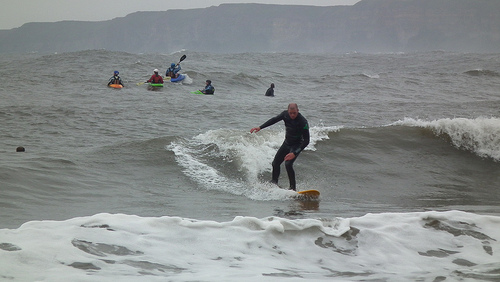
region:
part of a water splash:
[421, 115, 463, 148]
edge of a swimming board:
[297, 170, 319, 206]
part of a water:
[206, 196, 248, 238]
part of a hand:
[282, 145, 294, 162]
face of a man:
[278, 91, 300, 121]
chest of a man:
[285, 126, 301, 147]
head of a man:
[287, 99, 299, 114]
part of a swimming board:
[106, 82, 122, 92]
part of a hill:
[322, 14, 367, 49]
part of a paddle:
[174, 52, 189, 64]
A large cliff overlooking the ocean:
[14, 8, 491, 64]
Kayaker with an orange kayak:
[93, 62, 128, 94]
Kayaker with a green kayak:
[142, 62, 168, 97]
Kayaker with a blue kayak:
[161, 55, 203, 90]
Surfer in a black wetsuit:
[256, 97, 326, 222]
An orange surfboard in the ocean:
[279, 165, 341, 233]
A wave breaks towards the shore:
[107, 95, 492, 211]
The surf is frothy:
[25, 197, 465, 266]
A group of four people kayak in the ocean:
[76, 43, 223, 117]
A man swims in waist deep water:
[258, 77, 278, 99]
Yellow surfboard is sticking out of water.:
[288, 172, 330, 217]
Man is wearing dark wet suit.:
[257, 102, 337, 247]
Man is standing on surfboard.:
[264, 115, 355, 278]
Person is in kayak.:
[171, 52, 188, 96]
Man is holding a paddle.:
[172, 35, 199, 100]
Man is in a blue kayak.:
[164, 53, 202, 133]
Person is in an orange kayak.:
[104, 50, 144, 154]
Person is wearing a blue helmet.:
[106, 63, 149, 109]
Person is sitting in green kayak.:
[146, 50, 189, 130]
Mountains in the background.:
[66, 7, 389, 36]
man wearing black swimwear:
[254, 92, 332, 222]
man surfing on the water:
[256, 90, 342, 224]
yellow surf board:
[281, 186, 379, 221]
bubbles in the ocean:
[52, 207, 281, 263]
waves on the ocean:
[103, 95, 438, 185]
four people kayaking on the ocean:
[91, 36, 223, 102]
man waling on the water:
[252, 62, 282, 100]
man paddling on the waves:
[167, 33, 189, 109]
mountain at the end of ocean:
[53, 6, 426, 56]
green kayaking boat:
[141, 80, 173, 92]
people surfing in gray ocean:
[10, 7, 494, 224]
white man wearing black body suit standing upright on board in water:
[234, 80, 346, 222]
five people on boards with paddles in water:
[89, 32, 316, 104]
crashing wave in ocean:
[365, 61, 498, 258]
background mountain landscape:
[2, 0, 354, 53]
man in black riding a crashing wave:
[244, 92, 342, 218]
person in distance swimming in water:
[247, 60, 290, 106]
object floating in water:
[0, 117, 42, 167]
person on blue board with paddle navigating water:
[158, 29, 198, 91]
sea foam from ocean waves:
[51, 181, 306, 276]